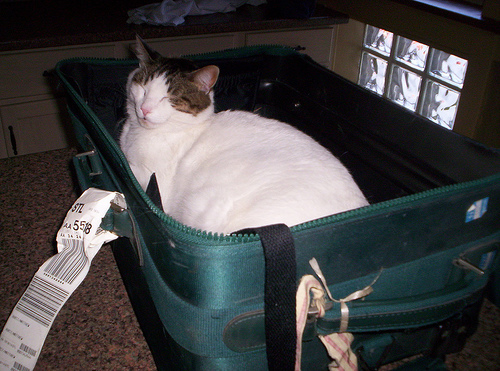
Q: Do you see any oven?
A: No, there are no ovens.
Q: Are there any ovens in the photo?
A: No, there are no ovens.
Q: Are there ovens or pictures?
A: No, there are no ovens or pictures.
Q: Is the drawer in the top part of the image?
A: Yes, the drawer is in the top of the image.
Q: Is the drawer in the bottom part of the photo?
A: No, the drawer is in the top of the image.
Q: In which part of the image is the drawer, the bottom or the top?
A: The drawer is in the top of the image.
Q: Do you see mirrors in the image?
A: No, there are no mirrors.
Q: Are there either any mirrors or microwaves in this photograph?
A: No, there are no mirrors or microwaves.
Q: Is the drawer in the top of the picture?
A: Yes, the drawer is in the top of the image.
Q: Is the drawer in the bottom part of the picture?
A: No, the drawer is in the top of the image.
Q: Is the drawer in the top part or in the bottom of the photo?
A: The drawer is in the top of the image.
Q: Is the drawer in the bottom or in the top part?
A: The drawer is in the top of the image.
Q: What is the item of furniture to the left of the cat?
A: The piece of furniture is a drawer.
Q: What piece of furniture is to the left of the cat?
A: The piece of furniture is a drawer.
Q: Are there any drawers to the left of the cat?
A: Yes, there is a drawer to the left of the cat.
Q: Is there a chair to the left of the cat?
A: No, there is a drawer to the left of the cat.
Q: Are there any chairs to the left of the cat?
A: No, there is a drawer to the left of the cat.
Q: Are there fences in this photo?
A: No, there are no fences.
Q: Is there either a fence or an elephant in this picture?
A: No, there are no fences or elephants.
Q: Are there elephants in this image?
A: No, there are no elephants.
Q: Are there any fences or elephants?
A: No, there are no elephants or fences.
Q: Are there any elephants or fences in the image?
A: No, there are no elephants or fences.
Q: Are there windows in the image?
A: Yes, there is a window.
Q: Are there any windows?
A: Yes, there is a window.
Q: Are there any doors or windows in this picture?
A: Yes, there is a window.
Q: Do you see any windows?
A: Yes, there is a window.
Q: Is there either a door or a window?
A: Yes, there is a window.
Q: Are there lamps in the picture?
A: No, there are no lamps.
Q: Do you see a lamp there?
A: No, there are no lamps.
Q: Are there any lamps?
A: No, there are no lamps.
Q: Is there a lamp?
A: No, there are no lamps.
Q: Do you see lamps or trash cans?
A: No, there are no lamps or trash cans.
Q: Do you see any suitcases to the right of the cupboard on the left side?
A: Yes, there is a suitcase to the right of the cupboard.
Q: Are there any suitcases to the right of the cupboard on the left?
A: Yes, there is a suitcase to the right of the cupboard.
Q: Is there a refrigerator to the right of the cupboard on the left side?
A: No, there is a suitcase to the right of the cupboard.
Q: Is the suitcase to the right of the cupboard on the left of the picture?
A: Yes, the suitcase is to the right of the cupboard.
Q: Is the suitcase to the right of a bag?
A: No, the suitcase is to the right of the cupboard.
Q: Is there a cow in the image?
A: No, there are no cows.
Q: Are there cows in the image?
A: No, there are no cows.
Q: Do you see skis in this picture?
A: No, there are no skis.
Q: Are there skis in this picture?
A: No, there are no skis.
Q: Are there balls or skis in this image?
A: No, there are no skis or balls.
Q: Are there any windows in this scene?
A: Yes, there is a window.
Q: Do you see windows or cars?
A: Yes, there is a window.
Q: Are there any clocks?
A: No, there are no clocks.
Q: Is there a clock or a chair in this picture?
A: No, there are no clocks or chairs.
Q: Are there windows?
A: Yes, there is a window.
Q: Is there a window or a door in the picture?
A: Yes, there is a window.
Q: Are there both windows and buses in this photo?
A: No, there is a window but no buses.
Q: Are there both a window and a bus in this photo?
A: No, there is a window but no buses.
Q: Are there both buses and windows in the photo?
A: No, there is a window but no buses.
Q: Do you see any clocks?
A: No, there are no clocks.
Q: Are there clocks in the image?
A: No, there are no clocks.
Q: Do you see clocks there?
A: No, there are no clocks.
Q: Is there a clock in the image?
A: No, there are no clocks.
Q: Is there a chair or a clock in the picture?
A: No, there are no clocks or chairs.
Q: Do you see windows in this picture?
A: Yes, there is a window.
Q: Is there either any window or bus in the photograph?
A: Yes, there is a window.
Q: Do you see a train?
A: No, there are no trains.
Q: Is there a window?
A: Yes, there is a window.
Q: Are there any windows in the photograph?
A: Yes, there is a window.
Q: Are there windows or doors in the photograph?
A: Yes, there is a window.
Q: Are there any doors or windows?
A: Yes, there is a window.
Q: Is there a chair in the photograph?
A: No, there are no chairs.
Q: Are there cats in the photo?
A: Yes, there is a cat.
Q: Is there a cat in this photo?
A: Yes, there is a cat.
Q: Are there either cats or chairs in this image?
A: Yes, there is a cat.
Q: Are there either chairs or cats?
A: Yes, there is a cat.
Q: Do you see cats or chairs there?
A: Yes, there is a cat.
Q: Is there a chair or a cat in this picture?
A: Yes, there is a cat.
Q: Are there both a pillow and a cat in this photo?
A: No, there is a cat but no pillows.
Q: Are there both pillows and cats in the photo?
A: No, there is a cat but no pillows.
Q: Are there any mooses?
A: No, there are no mooses.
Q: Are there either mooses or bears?
A: No, there are no mooses or bears.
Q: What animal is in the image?
A: The animal is a cat.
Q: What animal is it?
A: The animal is a cat.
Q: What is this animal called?
A: That is a cat.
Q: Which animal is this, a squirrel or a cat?
A: That is a cat.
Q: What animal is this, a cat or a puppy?
A: This is a cat.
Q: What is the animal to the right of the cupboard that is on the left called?
A: The animal is a cat.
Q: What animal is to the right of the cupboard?
A: The animal is a cat.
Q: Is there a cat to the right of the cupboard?
A: Yes, there is a cat to the right of the cupboard.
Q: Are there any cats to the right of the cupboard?
A: Yes, there is a cat to the right of the cupboard.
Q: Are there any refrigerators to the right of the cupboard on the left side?
A: No, there is a cat to the right of the cupboard.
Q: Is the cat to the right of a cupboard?
A: Yes, the cat is to the right of a cupboard.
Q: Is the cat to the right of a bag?
A: No, the cat is to the right of a cupboard.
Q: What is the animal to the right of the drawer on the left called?
A: The animal is a cat.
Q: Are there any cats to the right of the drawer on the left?
A: Yes, there is a cat to the right of the drawer.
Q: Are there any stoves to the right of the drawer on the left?
A: No, there is a cat to the right of the drawer.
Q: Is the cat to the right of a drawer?
A: Yes, the cat is to the right of a drawer.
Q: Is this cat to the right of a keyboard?
A: No, the cat is to the right of a drawer.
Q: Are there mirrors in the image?
A: No, there are no mirrors.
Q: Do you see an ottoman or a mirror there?
A: No, there are no mirrors or ottomen.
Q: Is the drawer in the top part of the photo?
A: Yes, the drawer is in the top of the image.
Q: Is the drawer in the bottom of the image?
A: No, the drawer is in the top of the image.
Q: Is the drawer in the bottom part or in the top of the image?
A: The drawer is in the top of the image.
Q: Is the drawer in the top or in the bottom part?
A: The drawer is in the top of the image.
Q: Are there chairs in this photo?
A: No, there are no chairs.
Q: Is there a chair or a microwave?
A: No, there are no chairs or microwaves.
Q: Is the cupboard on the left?
A: Yes, the cupboard is on the left of the image.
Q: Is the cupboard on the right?
A: No, the cupboard is on the left of the image.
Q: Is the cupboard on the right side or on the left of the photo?
A: The cupboard is on the left of the image.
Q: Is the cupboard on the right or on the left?
A: The cupboard is on the left of the image.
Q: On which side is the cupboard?
A: The cupboard is on the left of the image.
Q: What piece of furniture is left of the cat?
A: The piece of furniture is a cupboard.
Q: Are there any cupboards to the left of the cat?
A: Yes, there is a cupboard to the left of the cat.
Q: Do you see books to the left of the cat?
A: No, there is a cupboard to the left of the cat.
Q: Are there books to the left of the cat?
A: No, there is a cupboard to the left of the cat.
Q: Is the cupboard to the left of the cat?
A: Yes, the cupboard is to the left of the cat.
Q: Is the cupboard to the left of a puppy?
A: No, the cupboard is to the left of the cat.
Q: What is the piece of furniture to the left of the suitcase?
A: The piece of furniture is a cupboard.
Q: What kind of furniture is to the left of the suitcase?
A: The piece of furniture is a cupboard.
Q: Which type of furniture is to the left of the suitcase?
A: The piece of furniture is a cupboard.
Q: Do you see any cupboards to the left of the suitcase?
A: Yes, there is a cupboard to the left of the suitcase.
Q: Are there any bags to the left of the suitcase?
A: No, there is a cupboard to the left of the suitcase.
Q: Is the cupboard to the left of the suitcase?
A: Yes, the cupboard is to the left of the suitcase.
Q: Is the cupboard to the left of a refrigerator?
A: No, the cupboard is to the left of the suitcase.